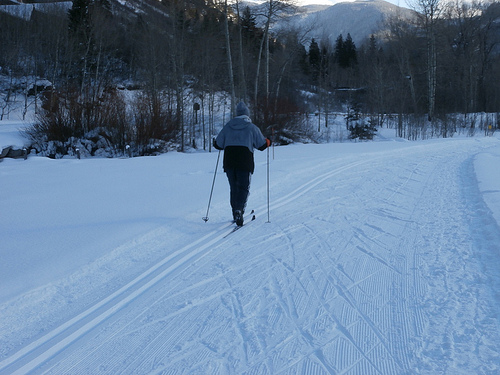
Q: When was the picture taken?
A: Daytime.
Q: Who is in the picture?
A: A skier.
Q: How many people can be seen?
A: 1.